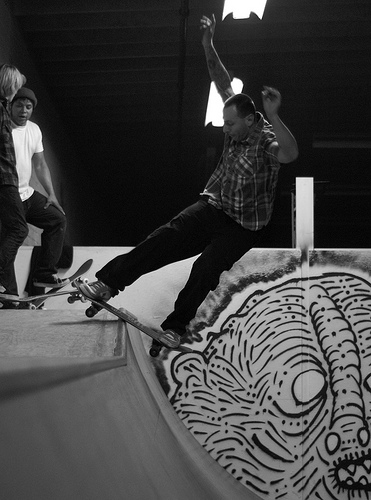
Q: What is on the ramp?
A: Mural.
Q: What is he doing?
A: Skateboarding.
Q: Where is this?
A: Skatepark.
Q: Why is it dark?
A: Nighttime.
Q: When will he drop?
A: Soon.